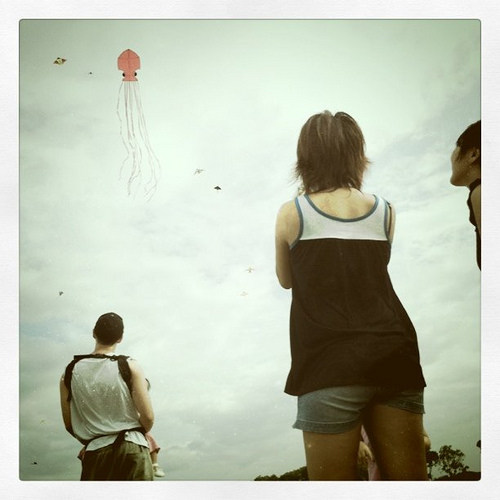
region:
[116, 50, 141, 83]
pink kite in sky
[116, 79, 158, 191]
pink tail of kite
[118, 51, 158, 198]
pink octopus kite in air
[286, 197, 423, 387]
black and white tank top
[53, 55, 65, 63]
orange and red kite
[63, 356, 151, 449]
white cotton tee shirt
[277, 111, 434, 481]
girl flying pink kite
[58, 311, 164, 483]
man looking at kites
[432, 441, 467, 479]
tree with green leaves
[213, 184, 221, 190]
black kite in sky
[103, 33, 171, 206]
red kite with tails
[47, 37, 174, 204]
kites in a cloudy sky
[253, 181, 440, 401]
brown and white tank top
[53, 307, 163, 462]
back of man in white tshirt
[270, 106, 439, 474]
back of woman in shorts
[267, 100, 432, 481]
girl wearing shorts and tank top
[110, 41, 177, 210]
cloudy sky with a red kite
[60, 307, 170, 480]
back of man wearing a baby carrier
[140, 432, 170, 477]
toddlers leg with white shoe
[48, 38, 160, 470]
man watching kites in the sky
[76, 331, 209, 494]
the babby is strapped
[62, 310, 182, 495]
man is carrying ababy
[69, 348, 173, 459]
man has vest on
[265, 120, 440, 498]
woman has shorts on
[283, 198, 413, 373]
the vest is black and white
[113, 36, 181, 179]
the kite is in the air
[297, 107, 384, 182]
the hair is brown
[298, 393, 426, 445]
the shorts are grey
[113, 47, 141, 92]
the kite is orange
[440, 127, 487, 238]
she is looking up in the sky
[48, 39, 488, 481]
people looking a kite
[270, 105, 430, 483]
woman wears a tank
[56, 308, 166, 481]
man holds a baby in his chest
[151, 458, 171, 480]
shoe of a baby is white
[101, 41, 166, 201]
a red kite with long tails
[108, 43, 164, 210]
kite has several tails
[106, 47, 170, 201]
kite shape like an octopus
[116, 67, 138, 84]
eyes of an octopus kiet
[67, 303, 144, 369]
man has black hair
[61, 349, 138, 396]
black straps on shoulders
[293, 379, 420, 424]
The woman is wearing short shorts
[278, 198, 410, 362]
The woman is wearing a black and white shirt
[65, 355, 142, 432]
The man is wearing a white shirt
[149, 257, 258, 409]
The sky is cloudy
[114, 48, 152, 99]
A red kite in the sky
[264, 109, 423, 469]
A woman under a kite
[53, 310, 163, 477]
A man under a kite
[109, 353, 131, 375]
The man has a black strap around him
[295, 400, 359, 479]
The left leg of the woman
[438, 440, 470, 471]
A tree in the distance